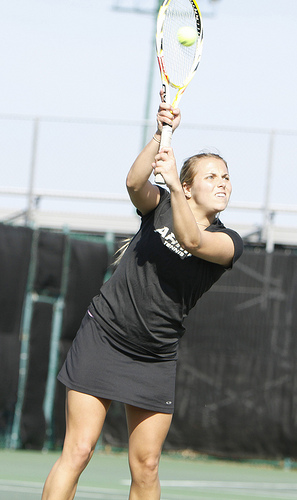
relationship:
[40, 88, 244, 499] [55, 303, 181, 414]
lady in dress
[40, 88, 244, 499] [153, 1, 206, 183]
lady playing tennis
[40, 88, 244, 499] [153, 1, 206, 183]
lady holding racket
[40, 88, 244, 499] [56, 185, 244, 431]
lady wearing clothes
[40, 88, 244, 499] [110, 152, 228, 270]
lady has brown hair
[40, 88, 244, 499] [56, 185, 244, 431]
lady wearing tshirt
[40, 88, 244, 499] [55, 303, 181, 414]
lady wearing a miniskirt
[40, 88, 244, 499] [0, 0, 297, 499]
lady in photo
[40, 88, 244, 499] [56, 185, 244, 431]
player wearing black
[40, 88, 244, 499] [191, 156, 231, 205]
woman making a face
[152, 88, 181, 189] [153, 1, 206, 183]
hands holding racket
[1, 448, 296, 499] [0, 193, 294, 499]
ground of court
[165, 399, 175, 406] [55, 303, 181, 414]
writing on her skirt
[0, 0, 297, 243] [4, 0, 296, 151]
pale sky above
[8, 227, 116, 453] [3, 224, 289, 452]
part of structure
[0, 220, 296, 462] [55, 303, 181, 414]
black short skirt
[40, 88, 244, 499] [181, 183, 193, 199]
woman's right ear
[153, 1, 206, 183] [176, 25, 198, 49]
racket hitting a tennis ball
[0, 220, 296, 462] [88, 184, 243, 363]
black skirt and top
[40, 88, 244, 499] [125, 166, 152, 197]
woman's bent elbow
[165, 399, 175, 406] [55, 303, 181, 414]
lettering on a skirt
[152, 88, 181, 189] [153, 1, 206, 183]
hands gripping a racket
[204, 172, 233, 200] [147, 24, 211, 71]
grimace accompanying a collision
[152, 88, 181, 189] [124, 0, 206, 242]
hand overhand volley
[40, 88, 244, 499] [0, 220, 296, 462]
female in black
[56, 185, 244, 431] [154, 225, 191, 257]
wearing a logo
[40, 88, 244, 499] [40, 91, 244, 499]
lady has a slender lady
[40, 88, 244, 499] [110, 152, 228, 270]
girl with hair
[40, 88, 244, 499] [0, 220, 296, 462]
player dressed in black